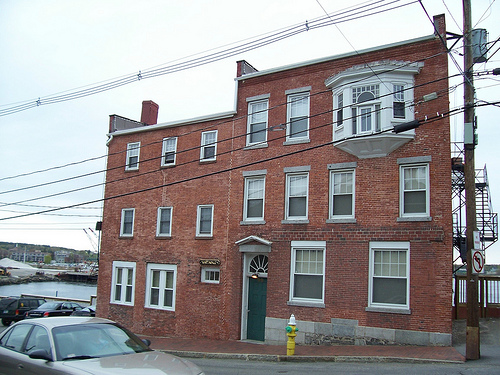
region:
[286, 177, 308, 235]
window on the building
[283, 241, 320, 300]
window on the building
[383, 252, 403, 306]
window on the building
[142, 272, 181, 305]
window on the building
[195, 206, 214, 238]
window on the building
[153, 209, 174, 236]
window on the building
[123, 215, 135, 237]
window on the building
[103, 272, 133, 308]
window on the building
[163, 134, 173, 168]
window on the building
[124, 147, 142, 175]
window on the building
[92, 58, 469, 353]
windows on the building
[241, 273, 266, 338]
green door on the building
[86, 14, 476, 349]
building is made of brick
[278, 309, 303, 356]
yellow, green, and white fire hydrant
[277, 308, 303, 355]
fire hydrant on the sidewalk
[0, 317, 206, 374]
car on the road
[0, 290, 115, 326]
a row of parked cars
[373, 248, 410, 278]
white lines on the window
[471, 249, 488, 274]
red, white, and black sign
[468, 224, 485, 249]
sign on a pole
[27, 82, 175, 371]
building beside the sea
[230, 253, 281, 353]
green door at the building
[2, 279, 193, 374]
cars parked at the side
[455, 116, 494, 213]
electrical post at the right side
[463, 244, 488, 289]
signage of no left turn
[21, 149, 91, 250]
electrical wires hanging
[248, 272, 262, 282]
light bulb turn on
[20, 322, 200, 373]
the car is color cream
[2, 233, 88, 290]
buildings near at the mountain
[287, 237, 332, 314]
the windows are painted into white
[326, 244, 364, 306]
A brown brick wall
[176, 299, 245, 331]
A brown brick wall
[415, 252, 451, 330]
A brown brick wall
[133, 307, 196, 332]
A brown brick wall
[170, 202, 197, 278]
A brown brick wall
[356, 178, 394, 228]
A brown brick wall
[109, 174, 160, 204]
A brown brick wall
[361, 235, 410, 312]
A white glass window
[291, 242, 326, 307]
A white glass window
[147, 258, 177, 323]
A white glass window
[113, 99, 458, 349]
red brick on house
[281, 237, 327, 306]
white frame on window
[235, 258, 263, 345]
door is dark green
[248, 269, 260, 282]
small light on door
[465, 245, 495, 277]
red and white sign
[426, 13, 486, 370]
sign on brown telephone pole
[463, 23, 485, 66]
transformer atop telephone pole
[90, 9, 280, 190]
power lines near house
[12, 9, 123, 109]
blue and grey sky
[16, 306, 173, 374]
grey car outside house